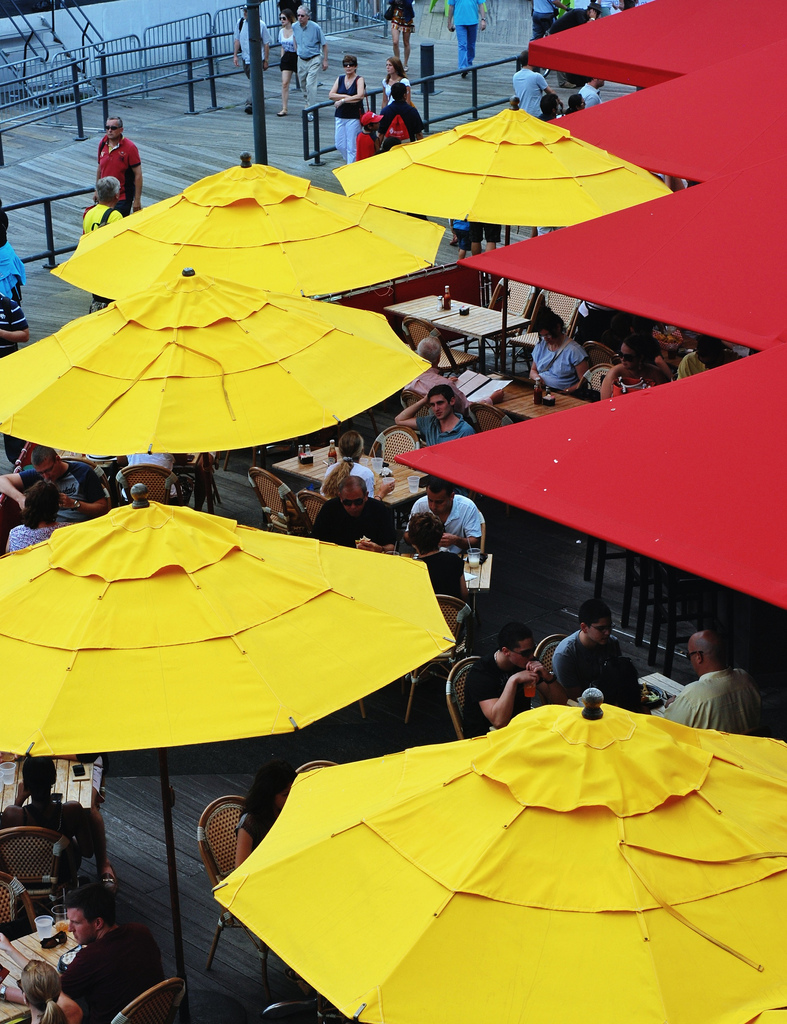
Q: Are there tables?
A: Yes, there is a table.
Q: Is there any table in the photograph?
A: Yes, there is a table.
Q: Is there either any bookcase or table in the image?
A: Yes, there is a table.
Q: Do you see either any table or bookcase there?
A: Yes, there is a table.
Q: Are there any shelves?
A: No, there are no shelves.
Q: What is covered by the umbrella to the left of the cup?
A: The table is covered by the umbrella.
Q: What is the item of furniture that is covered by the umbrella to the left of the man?
A: The piece of furniture is a table.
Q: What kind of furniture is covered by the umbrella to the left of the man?
A: The piece of furniture is a table.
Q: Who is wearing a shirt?
A: The man is wearing a shirt.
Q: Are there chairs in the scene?
A: Yes, there is a chair.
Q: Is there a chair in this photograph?
A: Yes, there is a chair.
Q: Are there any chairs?
A: Yes, there is a chair.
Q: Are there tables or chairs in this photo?
A: Yes, there is a chair.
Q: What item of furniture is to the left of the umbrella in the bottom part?
A: The piece of furniture is a chair.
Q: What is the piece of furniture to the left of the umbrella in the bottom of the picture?
A: The piece of furniture is a chair.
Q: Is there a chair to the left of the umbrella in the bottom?
A: Yes, there is a chair to the left of the umbrella.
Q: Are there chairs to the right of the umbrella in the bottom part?
A: No, the chair is to the left of the umbrella.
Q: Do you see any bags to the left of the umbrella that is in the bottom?
A: No, there is a chair to the left of the umbrella.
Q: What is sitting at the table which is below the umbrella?
A: The chair is sitting at the table.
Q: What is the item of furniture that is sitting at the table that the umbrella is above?
A: The piece of furniture is a chair.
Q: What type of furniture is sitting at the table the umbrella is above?
A: The piece of furniture is a chair.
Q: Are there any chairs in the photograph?
A: Yes, there is a chair.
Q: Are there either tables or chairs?
A: Yes, there is a chair.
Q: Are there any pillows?
A: No, there are no pillows.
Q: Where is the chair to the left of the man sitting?
A: The chair is sitting at the table.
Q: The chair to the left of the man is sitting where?
A: The chair is sitting at the table.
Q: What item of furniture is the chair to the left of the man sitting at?
A: The chair is sitting at the table.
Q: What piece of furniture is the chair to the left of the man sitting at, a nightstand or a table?
A: The chair is sitting at a table.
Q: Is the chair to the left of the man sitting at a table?
A: Yes, the chair is sitting at a table.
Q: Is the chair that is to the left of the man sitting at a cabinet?
A: No, the chair is sitting at a table.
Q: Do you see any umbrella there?
A: Yes, there is an umbrella.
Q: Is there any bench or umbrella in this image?
A: Yes, there is an umbrella.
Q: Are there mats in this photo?
A: No, there are no mats.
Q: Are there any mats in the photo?
A: No, there are no mats.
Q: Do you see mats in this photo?
A: No, there are no mats.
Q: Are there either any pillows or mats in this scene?
A: No, there are no mats or pillows.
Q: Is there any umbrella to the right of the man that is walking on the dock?
A: Yes, there is an umbrella to the right of the man.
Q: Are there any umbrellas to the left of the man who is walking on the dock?
A: No, the umbrella is to the right of the man.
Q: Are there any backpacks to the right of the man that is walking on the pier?
A: No, there is an umbrella to the right of the man.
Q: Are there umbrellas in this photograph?
A: Yes, there is an umbrella.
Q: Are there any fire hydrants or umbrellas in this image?
A: Yes, there is an umbrella.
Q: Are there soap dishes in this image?
A: No, there are no soap dishes.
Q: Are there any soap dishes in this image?
A: No, there are no soap dishes.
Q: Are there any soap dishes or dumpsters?
A: No, there are no soap dishes or dumpsters.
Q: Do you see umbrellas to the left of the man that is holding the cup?
A: Yes, there is an umbrella to the left of the man.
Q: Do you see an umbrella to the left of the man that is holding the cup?
A: Yes, there is an umbrella to the left of the man.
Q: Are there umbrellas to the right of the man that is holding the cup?
A: No, the umbrella is to the left of the man.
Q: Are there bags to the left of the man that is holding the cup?
A: No, there is an umbrella to the left of the man.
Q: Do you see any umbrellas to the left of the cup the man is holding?
A: Yes, there is an umbrella to the left of the cup.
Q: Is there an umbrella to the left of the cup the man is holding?
A: Yes, there is an umbrella to the left of the cup.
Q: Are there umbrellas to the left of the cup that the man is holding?
A: Yes, there is an umbrella to the left of the cup.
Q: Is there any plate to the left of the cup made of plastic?
A: No, there is an umbrella to the left of the cup.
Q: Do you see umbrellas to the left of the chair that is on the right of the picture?
A: Yes, there is an umbrella to the left of the chair.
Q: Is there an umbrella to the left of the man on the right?
A: Yes, there is an umbrella to the left of the man.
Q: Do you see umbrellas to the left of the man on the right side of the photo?
A: Yes, there is an umbrella to the left of the man.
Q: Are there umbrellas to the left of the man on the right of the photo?
A: Yes, there is an umbrella to the left of the man.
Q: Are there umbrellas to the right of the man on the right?
A: No, the umbrella is to the left of the man.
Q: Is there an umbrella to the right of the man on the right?
A: No, the umbrella is to the left of the man.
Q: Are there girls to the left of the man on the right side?
A: No, there is an umbrella to the left of the man.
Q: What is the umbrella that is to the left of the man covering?
A: The umbrella is covering the table.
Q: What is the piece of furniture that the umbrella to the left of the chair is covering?
A: The piece of furniture is a table.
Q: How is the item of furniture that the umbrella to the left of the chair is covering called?
A: The piece of furniture is a table.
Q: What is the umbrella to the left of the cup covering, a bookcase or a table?
A: The umbrella is covering a table.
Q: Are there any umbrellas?
A: Yes, there is an umbrella.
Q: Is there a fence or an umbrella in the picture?
A: Yes, there is an umbrella.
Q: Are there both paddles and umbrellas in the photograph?
A: No, there is an umbrella but no paddles.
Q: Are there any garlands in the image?
A: No, there are no garlands.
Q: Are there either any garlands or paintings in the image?
A: No, there are no garlands or paintings.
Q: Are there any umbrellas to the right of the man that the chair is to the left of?
A: Yes, there is an umbrella to the right of the man.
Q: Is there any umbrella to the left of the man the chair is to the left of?
A: No, the umbrella is to the right of the man.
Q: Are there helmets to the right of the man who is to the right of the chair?
A: No, there is an umbrella to the right of the man.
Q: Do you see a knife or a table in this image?
A: Yes, there is a table.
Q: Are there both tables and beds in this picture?
A: No, there is a table but no beds.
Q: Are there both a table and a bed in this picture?
A: No, there is a table but no beds.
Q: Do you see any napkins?
A: No, there are no napkins.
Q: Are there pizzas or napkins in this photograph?
A: No, there are no napkins or pizzas.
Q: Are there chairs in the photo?
A: Yes, there is a chair.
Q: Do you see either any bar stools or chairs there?
A: Yes, there is a chair.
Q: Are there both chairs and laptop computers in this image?
A: No, there is a chair but no laptops.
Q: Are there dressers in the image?
A: No, there are no dressers.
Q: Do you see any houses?
A: No, there are no houses.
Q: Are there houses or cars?
A: No, there are no houses or cars.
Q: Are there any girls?
A: No, there are no girls.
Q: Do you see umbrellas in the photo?
A: Yes, there is an umbrella.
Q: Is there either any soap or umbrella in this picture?
A: Yes, there is an umbrella.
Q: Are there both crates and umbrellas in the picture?
A: No, there is an umbrella but no crates.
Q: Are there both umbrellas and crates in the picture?
A: No, there is an umbrella but no crates.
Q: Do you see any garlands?
A: No, there are no garlands.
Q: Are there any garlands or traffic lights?
A: No, there are no garlands or traffic lights.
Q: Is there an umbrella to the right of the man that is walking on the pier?
A: Yes, there is an umbrella to the right of the man.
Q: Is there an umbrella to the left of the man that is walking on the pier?
A: No, the umbrella is to the right of the man.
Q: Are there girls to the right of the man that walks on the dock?
A: No, there is an umbrella to the right of the man.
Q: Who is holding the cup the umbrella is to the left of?
A: The man is holding the cup.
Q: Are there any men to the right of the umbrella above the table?
A: Yes, there is a man to the right of the umbrella.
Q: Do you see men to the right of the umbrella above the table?
A: Yes, there is a man to the right of the umbrella.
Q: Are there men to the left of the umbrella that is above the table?
A: No, the man is to the right of the umbrella.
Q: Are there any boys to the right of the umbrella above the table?
A: No, there is a man to the right of the umbrella.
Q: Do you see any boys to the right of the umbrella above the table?
A: No, there is a man to the right of the umbrella.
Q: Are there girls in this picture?
A: No, there are no girls.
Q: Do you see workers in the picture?
A: No, there are no workers.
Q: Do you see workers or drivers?
A: No, there are no workers or drivers.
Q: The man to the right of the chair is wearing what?
A: The man is wearing a shirt.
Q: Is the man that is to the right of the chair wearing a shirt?
A: Yes, the man is wearing a shirt.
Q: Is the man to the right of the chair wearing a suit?
A: No, the man is wearing a shirt.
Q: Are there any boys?
A: No, there are no boys.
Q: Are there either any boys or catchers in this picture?
A: No, there are no boys or catchers.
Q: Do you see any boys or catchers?
A: No, there are no boys or catchers.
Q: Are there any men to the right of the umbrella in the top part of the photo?
A: No, the man is to the left of the umbrella.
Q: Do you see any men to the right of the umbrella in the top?
A: No, the man is to the left of the umbrella.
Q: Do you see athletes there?
A: No, there are no athletes.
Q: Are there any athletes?
A: No, there are no athletes.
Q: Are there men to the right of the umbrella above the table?
A: Yes, there is a man to the right of the umbrella.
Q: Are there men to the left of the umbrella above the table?
A: No, the man is to the right of the umbrella.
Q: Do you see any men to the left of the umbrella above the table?
A: No, the man is to the right of the umbrella.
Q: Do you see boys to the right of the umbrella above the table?
A: No, there is a man to the right of the umbrella.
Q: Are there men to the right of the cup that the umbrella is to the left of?
A: Yes, there is a man to the right of the cup.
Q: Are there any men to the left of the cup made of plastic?
A: No, the man is to the right of the cup.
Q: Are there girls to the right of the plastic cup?
A: No, there is a man to the right of the cup.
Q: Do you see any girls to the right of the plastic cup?
A: No, there is a man to the right of the cup.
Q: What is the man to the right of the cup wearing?
A: The man is wearing a shirt.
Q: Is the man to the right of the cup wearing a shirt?
A: Yes, the man is wearing a shirt.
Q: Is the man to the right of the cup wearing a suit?
A: No, the man is wearing a shirt.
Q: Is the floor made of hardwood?
A: Yes, the floor is made of hardwood.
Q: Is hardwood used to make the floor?
A: Yes, the floor is made of hardwood.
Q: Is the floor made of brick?
A: No, the floor is made of hardwood.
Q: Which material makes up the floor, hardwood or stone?
A: The floor is made of hardwood.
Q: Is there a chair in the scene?
A: Yes, there is a chair.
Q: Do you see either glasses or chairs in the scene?
A: Yes, there is a chair.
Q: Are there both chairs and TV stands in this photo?
A: No, there is a chair but no TV stands.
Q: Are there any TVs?
A: No, there are no tvs.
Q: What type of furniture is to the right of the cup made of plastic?
A: The piece of furniture is a chair.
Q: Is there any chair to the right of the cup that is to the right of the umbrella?
A: Yes, there is a chair to the right of the cup.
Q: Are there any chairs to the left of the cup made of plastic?
A: No, the chair is to the right of the cup.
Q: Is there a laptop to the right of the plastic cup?
A: No, there is a chair to the right of the cup.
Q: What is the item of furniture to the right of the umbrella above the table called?
A: The piece of furniture is a chair.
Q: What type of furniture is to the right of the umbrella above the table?
A: The piece of furniture is a chair.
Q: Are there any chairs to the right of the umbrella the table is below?
A: Yes, there is a chair to the right of the umbrella.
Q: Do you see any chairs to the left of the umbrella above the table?
A: No, the chair is to the right of the umbrella.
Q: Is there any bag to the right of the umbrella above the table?
A: No, there is a chair to the right of the umbrella.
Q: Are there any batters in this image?
A: No, there are no batters.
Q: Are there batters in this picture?
A: No, there are no batters.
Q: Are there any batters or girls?
A: No, there are no batters or girls.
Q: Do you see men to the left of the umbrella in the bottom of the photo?
A: Yes, there is a man to the left of the umbrella.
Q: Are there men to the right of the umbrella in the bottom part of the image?
A: No, the man is to the left of the umbrella.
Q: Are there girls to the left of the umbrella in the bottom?
A: No, there is a man to the left of the umbrella.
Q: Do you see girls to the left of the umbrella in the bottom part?
A: No, there is a man to the left of the umbrella.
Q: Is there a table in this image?
A: Yes, there is a table.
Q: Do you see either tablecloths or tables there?
A: Yes, there is a table.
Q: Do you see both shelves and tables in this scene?
A: No, there is a table but no shelves.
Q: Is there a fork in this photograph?
A: No, there are no forks.